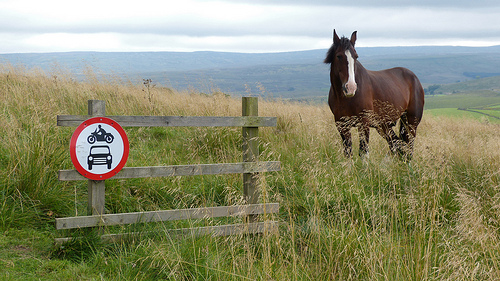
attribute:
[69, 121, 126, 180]
sign — red, white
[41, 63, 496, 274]
grass — dry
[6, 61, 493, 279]
grass — tall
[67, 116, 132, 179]
sign — a picture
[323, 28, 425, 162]
horse — brown, white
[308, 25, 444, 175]
horse — white, brown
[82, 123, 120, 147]
motorbike — picture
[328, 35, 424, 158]
horse — brown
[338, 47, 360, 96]
nose — white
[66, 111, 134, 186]
sign — round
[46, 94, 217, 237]
post — brown, wooden, fence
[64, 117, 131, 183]
sign — red, white, black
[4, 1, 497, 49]
gray sky — cloudy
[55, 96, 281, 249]
post — wooden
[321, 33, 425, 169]
horse — standing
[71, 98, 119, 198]
sign — round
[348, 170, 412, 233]
grass — green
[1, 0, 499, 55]
sky — very cloudy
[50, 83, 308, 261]
fence — wooden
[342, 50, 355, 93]
face — white